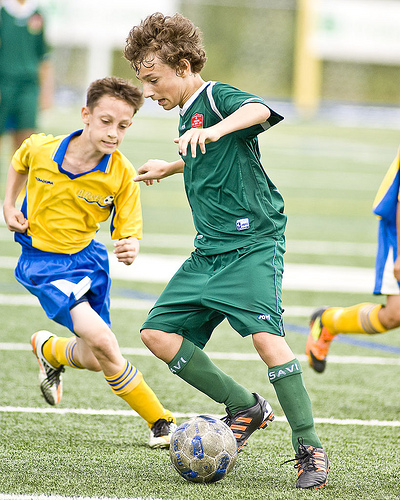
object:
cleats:
[149, 417, 178, 448]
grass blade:
[111, 473, 119, 482]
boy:
[1, 76, 179, 449]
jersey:
[11, 133, 143, 254]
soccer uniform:
[138, 81, 288, 350]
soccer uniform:
[10, 131, 145, 255]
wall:
[186, 69, 248, 134]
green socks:
[168, 335, 322, 454]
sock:
[103, 360, 175, 428]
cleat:
[280, 436, 330, 489]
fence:
[166, 408, 240, 484]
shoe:
[279, 436, 329, 489]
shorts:
[13, 239, 112, 339]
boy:
[123, 8, 330, 490]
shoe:
[218, 392, 274, 449]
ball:
[170, 415, 237, 482]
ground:
[0, 120, 398, 498]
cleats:
[30, 329, 64, 405]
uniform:
[136, 81, 287, 339]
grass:
[2, 297, 398, 496]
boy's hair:
[85, 76, 144, 115]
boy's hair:
[123, 12, 207, 77]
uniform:
[9, 130, 141, 331]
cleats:
[220, 392, 274, 454]